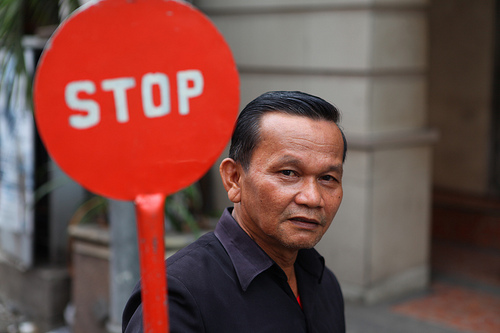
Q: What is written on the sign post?
A: STOP.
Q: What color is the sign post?
A: Red.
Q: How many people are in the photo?
A: 1.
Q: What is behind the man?
A: A wall.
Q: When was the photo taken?
A: Day time.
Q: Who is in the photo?
A: A man.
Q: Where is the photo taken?
A: A city sidewalk.